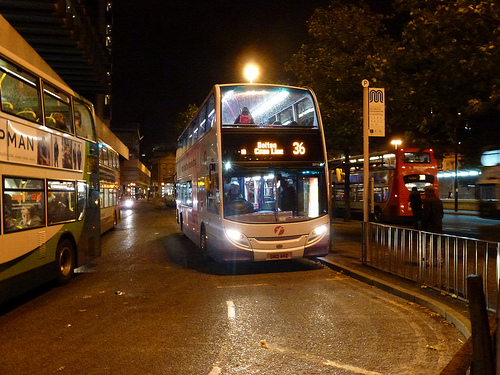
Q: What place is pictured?
A: It is a street.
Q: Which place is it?
A: It is a street.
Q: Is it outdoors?
A: Yes, it is outdoors.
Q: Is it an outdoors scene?
A: Yes, it is outdoors.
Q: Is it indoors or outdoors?
A: It is outdoors.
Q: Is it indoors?
A: No, it is outdoors.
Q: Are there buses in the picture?
A: Yes, there is a bus.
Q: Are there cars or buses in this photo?
A: Yes, there is a bus.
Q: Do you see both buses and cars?
A: No, there is a bus but no cars.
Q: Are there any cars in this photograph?
A: No, there are no cars.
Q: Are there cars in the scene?
A: No, there are no cars.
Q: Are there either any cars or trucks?
A: No, there are no cars or trucks.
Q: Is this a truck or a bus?
A: This is a bus.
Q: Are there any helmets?
A: No, there are no helmets.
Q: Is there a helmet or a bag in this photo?
A: No, there are no helmets or bags.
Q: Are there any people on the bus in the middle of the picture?
A: Yes, there is a person on the bus.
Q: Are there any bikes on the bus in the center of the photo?
A: No, there is a person on the bus.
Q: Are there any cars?
A: No, there are no cars.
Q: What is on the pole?
A: The sign is on the pole.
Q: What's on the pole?
A: The sign is on the pole.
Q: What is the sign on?
A: The sign is on the pole.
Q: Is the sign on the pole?
A: Yes, the sign is on the pole.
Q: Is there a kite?
A: No, there are no kites.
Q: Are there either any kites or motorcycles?
A: No, there are no kites or motorcycles.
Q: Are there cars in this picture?
A: No, there are no cars.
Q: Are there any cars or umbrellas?
A: No, there are no cars or umbrellas.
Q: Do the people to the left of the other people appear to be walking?
A: Yes, the people are walking.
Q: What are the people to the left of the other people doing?
A: The people are walking.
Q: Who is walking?
A: The people are walking.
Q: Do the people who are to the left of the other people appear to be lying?
A: No, the people are walking.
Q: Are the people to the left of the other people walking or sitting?
A: The people are walking.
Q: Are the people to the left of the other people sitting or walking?
A: The people are walking.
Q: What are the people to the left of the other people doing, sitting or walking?
A: The people are walking.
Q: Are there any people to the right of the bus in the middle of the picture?
A: Yes, there are people to the right of the bus.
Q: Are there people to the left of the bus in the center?
A: No, the people are to the right of the bus.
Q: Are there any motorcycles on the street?
A: No, there are people on the street.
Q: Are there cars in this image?
A: No, there are no cars.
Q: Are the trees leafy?
A: Yes, the trees are leafy.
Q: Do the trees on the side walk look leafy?
A: Yes, the trees are leafy.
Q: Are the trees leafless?
A: No, the trees are leafy.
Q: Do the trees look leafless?
A: No, the trees are leafy.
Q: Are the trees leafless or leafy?
A: The trees are leafy.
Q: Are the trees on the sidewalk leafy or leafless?
A: The trees are leafy.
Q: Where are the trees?
A: The trees are on the sidewalk.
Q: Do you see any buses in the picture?
A: Yes, there is a bus.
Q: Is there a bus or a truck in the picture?
A: Yes, there is a bus.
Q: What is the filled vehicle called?
A: The vehicle is a bus.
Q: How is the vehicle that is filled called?
A: The vehicle is a bus.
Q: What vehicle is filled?
A: The vehicle is a bus.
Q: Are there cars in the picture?
A: No, there are no cars.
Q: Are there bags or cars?
A: No, there are no cars or bags.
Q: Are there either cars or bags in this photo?
A: No, there are no cars or bags.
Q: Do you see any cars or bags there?
A: No, there are no cars or bags.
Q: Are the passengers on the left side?
A: Yes, the passengers are on the left of the image.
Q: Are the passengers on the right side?
A: No, the passengers are on the left of the image.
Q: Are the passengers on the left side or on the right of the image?
A: The passengers are on the left of the image.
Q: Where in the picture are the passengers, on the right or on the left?
A: The passengers are on the left of the image.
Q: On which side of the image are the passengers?
A: The passengers are on the left of the image.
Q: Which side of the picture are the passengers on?
A: The passengers are on the left of the image.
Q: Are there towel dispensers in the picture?
A: No, there are no towel dispensers.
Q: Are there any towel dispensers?
A: No, there are no towel dispensers.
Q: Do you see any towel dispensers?
A: No, there are no towel dispensers.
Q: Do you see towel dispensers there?
A: No, there are no towel dispensers.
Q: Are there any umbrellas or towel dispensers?
A: No, there are no towel dispensers or umbrellas.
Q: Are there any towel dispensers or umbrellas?
A: No, there are no towel dispensers or umbrellas.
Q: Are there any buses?
A: Yes, there is a bus.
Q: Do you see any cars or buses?
A: Yes, there is a bus.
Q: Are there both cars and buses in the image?
A: No, there is a bus but no cars.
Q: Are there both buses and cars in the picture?
A: No, there is a bus but no cars.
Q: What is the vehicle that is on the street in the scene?
A: The vehicle is a bus.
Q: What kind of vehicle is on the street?
A: The vehicle is a bus.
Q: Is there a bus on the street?
A: Yes, there is a bus on the street.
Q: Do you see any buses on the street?
A: Yes, there is a bus on the street.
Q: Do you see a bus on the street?
A: Yes, there is a bus on the street.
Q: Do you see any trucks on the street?
A: No, there is a bus on the street.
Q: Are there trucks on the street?
A: No, there is a bus on the street.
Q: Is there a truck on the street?
A: No, there is a bus on the street.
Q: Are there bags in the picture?
A: No, there are no bags.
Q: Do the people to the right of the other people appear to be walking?
A: Yes, the people are walking.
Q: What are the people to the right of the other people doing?
A: The people are walking.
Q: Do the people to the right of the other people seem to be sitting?
A: No, the people are walking.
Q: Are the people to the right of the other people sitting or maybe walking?
A: The people are walking.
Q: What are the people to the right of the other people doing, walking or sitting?
A: The people are walking.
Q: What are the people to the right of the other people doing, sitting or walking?
A: The people are walking.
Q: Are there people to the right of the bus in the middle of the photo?
A: Yes, there are people to the right of the bus.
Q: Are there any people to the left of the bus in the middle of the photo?
A: No, the people are to the right of the bus.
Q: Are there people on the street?
A: Yes, there are people on the street.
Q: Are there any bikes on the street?
A: No, there are people on the street.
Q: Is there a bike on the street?
A: No, there are people on the street.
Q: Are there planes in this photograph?
A: No, there are no planes.